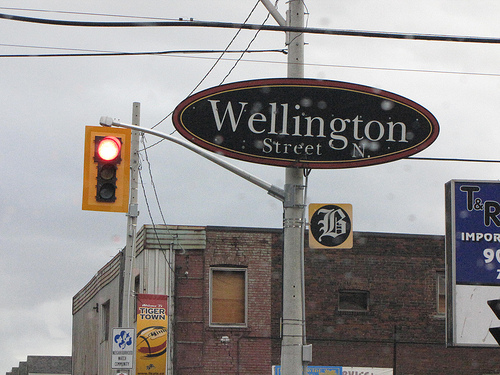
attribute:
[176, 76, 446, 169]
sign — black, large, oval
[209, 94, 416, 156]
lettering — white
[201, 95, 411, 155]
words — "Wellington Street", on a sign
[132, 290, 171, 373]
banner — with a picture of a football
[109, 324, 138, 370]
white/blue sign — "neighborhood watch"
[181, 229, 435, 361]
brick building — large, red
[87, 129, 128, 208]
traffic light — lit up red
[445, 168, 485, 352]
business sign — blue and white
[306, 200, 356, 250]
yellow/black sign — small, with ornate"B" on it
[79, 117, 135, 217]
traffic signal — at an intersection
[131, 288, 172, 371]
football banner — yellow and red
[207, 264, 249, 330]
window — boarded up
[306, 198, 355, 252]
black/yellow sign — with the letter b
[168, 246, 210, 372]
ladder — leading to the roof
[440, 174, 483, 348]
shop sign — blue and white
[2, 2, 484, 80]
power lines — crossing overhead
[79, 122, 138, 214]
yellow/stop light — on metal pole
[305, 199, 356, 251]
street sign — black and yellow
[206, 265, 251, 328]
window — boarded up with plywood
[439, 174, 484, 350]
advertising sign — blue and white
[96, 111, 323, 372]
street light — on metal pole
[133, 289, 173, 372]
advertising sign — red and yellow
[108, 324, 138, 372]
sign — blue, white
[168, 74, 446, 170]
street sign — on wellington sign, oval shaped, oval, black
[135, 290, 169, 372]
signage — red, yellow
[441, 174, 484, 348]
signage — blue, white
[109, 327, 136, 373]
street sign — white, blue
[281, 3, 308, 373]
pole — metal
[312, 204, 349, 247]
letter — white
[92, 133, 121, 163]
traffic light — red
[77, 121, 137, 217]
traffic light — aerial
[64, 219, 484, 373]
building — red, brick, brown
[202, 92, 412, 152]
word — white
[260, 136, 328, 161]
word — white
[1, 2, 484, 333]
sky — gray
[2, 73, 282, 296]
clouds — gray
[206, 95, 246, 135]
letter — white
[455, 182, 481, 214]
letter — black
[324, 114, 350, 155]
letter — white